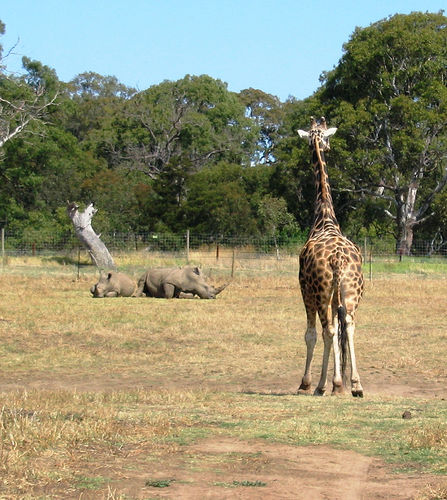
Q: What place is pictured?
A: It is a field.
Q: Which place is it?
A: It is a field.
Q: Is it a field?
A: Yes, it is a field.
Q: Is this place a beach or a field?
A: It is a field.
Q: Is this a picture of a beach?
A: No, the picture is showing a field.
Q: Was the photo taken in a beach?
A: No, the picture was taken in a field.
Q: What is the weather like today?
A: It is clear.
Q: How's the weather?
A: It is clear.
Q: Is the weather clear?
A: Yes, it is clear.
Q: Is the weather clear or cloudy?
A: It is clear.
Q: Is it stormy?
A: No, it is clear.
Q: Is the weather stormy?
A: No, it is clear.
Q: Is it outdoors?
A: Yes, it is outdoors.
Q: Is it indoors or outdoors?
A: It is outdoors.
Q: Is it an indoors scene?
A: No, it is outdoors.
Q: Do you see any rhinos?
A: Yes, there is a rhino.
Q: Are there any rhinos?
A: Yes, there is a rhino.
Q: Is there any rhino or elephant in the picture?
A: Yes, there is a rhino.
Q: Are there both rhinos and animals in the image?
A: Yes, there are both a rhino and an animal.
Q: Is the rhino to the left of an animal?
A: Yes, the rhino is to the left of an animal.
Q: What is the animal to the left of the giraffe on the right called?
A: The animal is a rhino.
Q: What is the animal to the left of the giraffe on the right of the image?
A: The animal is a rhino.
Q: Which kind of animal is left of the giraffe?
A: The animal is a rhino.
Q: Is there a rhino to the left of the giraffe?
A: Yes, there is a rhino to the left of the giraffe.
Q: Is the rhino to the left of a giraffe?
A: Yes, the rhino is to the left of a giraffe.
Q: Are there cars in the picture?
A: No, there are no cars.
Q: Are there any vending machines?
A: No, there are no vending machines.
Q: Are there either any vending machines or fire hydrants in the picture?
A: No, there are no vending machines or fire hydrants.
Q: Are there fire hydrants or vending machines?
A: No, there are no vending machines or fire hydrants.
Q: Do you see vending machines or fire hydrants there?
A: No, there are no vending machines or fire hydrants.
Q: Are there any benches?
A: No, there are no benches.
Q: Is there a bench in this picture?
A: No, there are no benches.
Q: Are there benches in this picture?
A: No, there are no benches.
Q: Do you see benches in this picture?
A: No, there are no benches.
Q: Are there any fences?
A: Yes, there is a fence.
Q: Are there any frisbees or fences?
A: Yes, there is a fence.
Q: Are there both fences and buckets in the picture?
A: No, there is a fence but no buckets.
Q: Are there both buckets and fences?
A: No, there is a fence but no buckets.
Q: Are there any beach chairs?
A: No, there are no beach chairs.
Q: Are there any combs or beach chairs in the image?
A: No, there are no beach chairs or combs.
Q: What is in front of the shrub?
A: The fence is in front of the shrub.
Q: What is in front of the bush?
A: The fence is in front of the shrub.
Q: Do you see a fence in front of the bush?
A: Yes, there is a fence in front of the bush.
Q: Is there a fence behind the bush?
A: No, the fence is in front of the bush.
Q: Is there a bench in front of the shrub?
A: No, there is a fence in front of the shrub.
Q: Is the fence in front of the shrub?
A: Yes, the fence is in front of the shrub.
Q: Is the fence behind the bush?
A: No, the fence is in front of the bush.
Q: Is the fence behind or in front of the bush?
A: The fence is in front of the bush.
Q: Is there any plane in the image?
A: No, there are no airplanes.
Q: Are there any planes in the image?
A: No, there are no planes.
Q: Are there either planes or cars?
A: No, there are no planes or cars.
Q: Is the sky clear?
A: Yes, the sky is clear.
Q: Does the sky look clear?
A: Yes, the sky is clear.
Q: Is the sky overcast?
A: No, the sky is clear.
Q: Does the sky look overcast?
A: No, the sky is clear.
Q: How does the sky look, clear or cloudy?
A: The sky is clear.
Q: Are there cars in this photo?
A: No, there are no cars.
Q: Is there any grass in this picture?
A: Yes, there is grass.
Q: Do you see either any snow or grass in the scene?
A: Yes, there is grass.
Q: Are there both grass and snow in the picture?
A: No, there is grass but no snow.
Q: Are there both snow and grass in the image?
A: No, there is grass but no snow.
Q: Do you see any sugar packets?
A: No, there are no sugar packets.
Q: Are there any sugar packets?
A: No, there are no sugar packets.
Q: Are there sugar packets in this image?
A: No, there are no sugar packets.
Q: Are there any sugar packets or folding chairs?
A: No, there are no sugar packets or folding chairs.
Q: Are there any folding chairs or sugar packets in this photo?
A: No, there are no sugar packets or folding chairs.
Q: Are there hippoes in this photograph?
A: Yes, there is a hippo.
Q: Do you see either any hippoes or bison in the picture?
A: Yes, there is a hippo.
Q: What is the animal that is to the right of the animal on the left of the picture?
A: The animal is a hippo.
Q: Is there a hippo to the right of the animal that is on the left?
A: Yes, there is a hippo to the right of the animal.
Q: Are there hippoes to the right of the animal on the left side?
A: Yes, there is a hippo to the right of the animal.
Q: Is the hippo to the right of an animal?
A: Yes, the hippo is to the right of an animal.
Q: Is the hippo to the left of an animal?
A: Yes, the hippo is to the left of an animal.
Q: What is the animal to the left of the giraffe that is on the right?
A: The animal is a hippo.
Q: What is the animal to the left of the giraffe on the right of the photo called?
A: The animal is a hippo.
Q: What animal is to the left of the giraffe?
A: The animal is a hippo.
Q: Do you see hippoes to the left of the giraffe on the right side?
A: Yes, there is a hippo to the left of the giraffe.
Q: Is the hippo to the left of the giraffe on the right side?
A: Yes, the hippo is to the left of the giraffe.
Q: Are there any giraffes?
A: Yes, there is a giraffe.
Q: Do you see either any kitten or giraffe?
A: Yes, there is a giraffe.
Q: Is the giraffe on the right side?
A: Yes, the giraffe is on the right of the image.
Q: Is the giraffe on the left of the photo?
A: No, the giraffe is on the right of the image.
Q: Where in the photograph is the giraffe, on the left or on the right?
A: The giraffe is on the right of the image.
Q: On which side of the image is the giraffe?
A: The giraffe is on the right of the image.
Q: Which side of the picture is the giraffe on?
A: The giraffe is on the right of the image.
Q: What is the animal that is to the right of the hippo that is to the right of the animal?
A: The animal is a giraffe.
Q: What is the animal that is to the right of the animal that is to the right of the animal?
A: The animal is a giraffe.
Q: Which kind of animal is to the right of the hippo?
A: The animal is a giraffe.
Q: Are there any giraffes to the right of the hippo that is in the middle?
A: Yes, there is a giraffe to the right of the hippo.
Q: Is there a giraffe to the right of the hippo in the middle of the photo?
A: Yes, there is a giraffe to the right of the hippo.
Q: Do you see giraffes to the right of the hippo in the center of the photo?
A: Yes, there is a giraffe to the right of the hippo.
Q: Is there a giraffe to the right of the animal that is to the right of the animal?
A: Yes, there is a giraffe to the right of the hippo.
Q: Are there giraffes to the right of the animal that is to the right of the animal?
A: Yes, there is a giraffe to the right of the hippo.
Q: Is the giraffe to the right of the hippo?
A: Yes, the giraffe is to the right of the hippo.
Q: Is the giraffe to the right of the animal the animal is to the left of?
A: Yes, the giraffe is to the right of the hippo.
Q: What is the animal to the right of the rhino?
A: The animal is a giraffe.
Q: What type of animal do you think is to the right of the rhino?
A: The animal is a giraffe.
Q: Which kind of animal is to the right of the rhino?
A: The animal is a giraffe.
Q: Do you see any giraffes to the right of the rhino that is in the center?
A: Yes, there is a giraffe to the right of the rhino.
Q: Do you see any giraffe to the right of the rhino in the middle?
A: Yes, there is a giraffe to the right of the rhino.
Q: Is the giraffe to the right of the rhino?
A: Yes, the giraffe is to the right of the rhino.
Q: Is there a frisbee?
A: No, there are no frisbees.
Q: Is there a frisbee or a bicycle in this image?
A: No, there are no frisbees or bicycles.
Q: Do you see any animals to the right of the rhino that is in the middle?
A: Yes, there is an animal to the right of the rhino.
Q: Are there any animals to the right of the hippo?
A: Yes, there is an animal to the right of the hippo.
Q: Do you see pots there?
A: No, there are no pots.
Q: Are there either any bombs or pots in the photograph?
A: No, there are no pots or bombs.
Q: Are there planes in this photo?
A: No, there are no planes.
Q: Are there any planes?
A: No, there are no planes.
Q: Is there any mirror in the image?
A: No, there are no mirrors.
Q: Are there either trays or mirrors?
A: No, there are no mirrors or trays.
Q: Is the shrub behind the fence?
A: Yes, the shrub is behind the fence.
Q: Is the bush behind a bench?
A: No, the bush is behind the fence.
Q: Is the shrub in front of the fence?
A: No, the shrub is behind the fence.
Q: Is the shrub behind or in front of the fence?
A: The shrub is behind the fence.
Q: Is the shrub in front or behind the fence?
A: The shrub is behind the fence.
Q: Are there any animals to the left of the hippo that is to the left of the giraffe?
A: Yes, there is an animal to the left of the hippo.